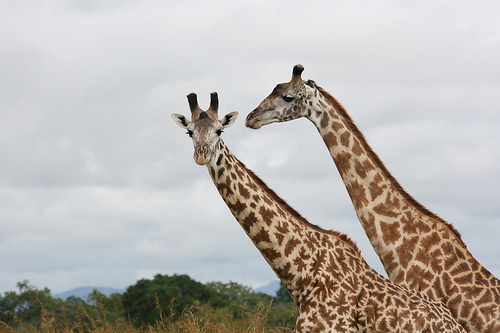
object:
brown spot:
[395, 235, 420, 268]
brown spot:
[372, 191, 401, 218]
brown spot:
[379, 221, 401, 247]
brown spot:
[453, 272, 472, 285]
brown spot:
[420, 231, 442, 253]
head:
[170, 91, 238, 165]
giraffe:
[170, 91, 469, 333]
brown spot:
[242, 211, 260, 234]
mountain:
[51, 285, 128, 305]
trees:
[52, 273, 225, 329]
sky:
[0, 0, 497, 275]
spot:
[238, 182, 251, 199]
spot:
[258, 204, 278, 226]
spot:
[275, 220, 291, 235]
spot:
[273, 232, 285, 247]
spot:
[283, 237, 301, 258]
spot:
[251, 227, 272, 245]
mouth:
[244, 108, 279, 130]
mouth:
[192, 144, 212, 165]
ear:
[171, 113, 189, 129]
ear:
[221, 111, 239, 130]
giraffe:
[244, 63, 499, 333]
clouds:
[2, 0, 500, 265]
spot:
[395, 236, 420, 269]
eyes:
[186, 128, 194, 137]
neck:
[205, 145, 358, 293]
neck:
[312, 92, 462, 279]